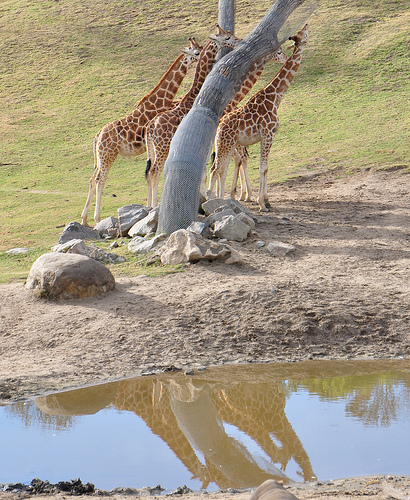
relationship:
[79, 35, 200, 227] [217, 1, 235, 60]
giraffe standing next to tree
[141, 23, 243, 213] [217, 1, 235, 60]
giraffe standing next to tree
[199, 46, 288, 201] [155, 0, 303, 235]
giraffe standing next to tree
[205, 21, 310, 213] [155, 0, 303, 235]
giraffe standing next to tree